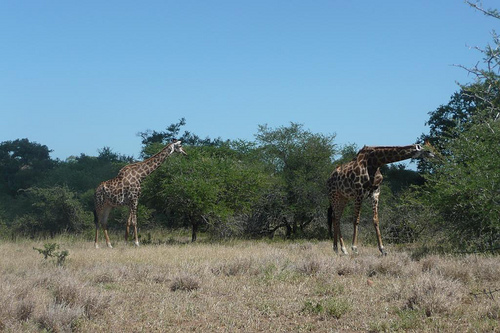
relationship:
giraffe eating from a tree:
[312, 121, 441, 302] [425, 11, 484, 271]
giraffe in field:
[75, 123, 178, 236] [8, 221, 481, 313]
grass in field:
[8, 232, 483, 326] [5, 213, 484, 329]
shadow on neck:
[369, 143, 412, 161] [359, 137, 418, 177]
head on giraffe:
[159, 129, 196, 162] [69, 122, 189, 282]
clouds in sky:
[49, 22, 450, 124] [27, 15, 475, 169]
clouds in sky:
[33, 29, 462, 92] [14, 27, 477, 116]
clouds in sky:
[12, 12, 452, 162] [8, 22, 484, 119]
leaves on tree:
[240, 136, 305, 212] [162, 117, 313, 235]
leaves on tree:
[146, 126, 299, 239] [175, 125, 266, 232]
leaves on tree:
[423, 120, 468, 190] [406, 60, 487, 258]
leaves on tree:
[425, 101, 485, 195] [410, 60, 499, 240]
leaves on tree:
[44, 156, 85, 190] [18, 129, 94, 207]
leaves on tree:
[20, 130, 75, 245] [7, 139, 55, 191]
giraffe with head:
[75, 123, 178, 236] [149, 117, 175, 147]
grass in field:
[104, 232, 321, 326] [62, 237, 343, 316]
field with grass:
[62, 237, 343, 316] [104, 232, 321, 326]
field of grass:
[62, 237, 343, 316] [96, 223, 442, 313]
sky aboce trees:
[89, 17, 344, 120] [121, 110, 272, 245]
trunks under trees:
[270, 205, 316, 243] [235, 103, 335, 243]